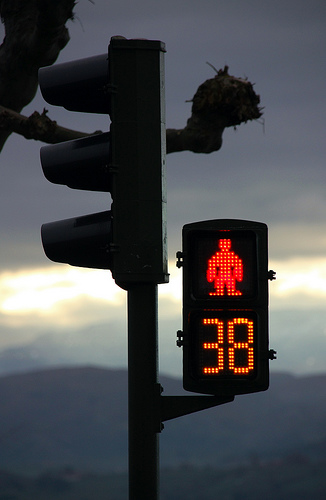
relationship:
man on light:
[206, 237, 241, 297] [184, 211, 280, 385]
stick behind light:
[0, 105, 100, 147] [28, 41, 171, 289]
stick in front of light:
[171, 72, 267, 150] [28, 41, 171, 289]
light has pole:
[184, 211, 280, 385] [153, 393, 229, 418]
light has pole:
[28, 41, 171, 289] [113, 285, 170, 495]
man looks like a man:
[206, 237, 241, 297] [206, 237, 256, 291]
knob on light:
[265, 267, 279, 281] [184, 211, 280, 385]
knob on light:
[259, 346, 282, 364] [184, 211, 280, 385]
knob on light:
[174, 248, 190, 258] [184, 211, 280, 385]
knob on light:
[174, 259, 191, 271] [184, 211, 280, 385]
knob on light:
[175, 325, 187, 338] [184, 211, 280, 385]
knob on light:
[178, 339, 184, 347] [184, 211, 280, 385]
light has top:
[28, 41, 171, 289] [39, 50, 129, 110]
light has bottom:
[28, 41, 171, 289] [42, 206, 129, 273]